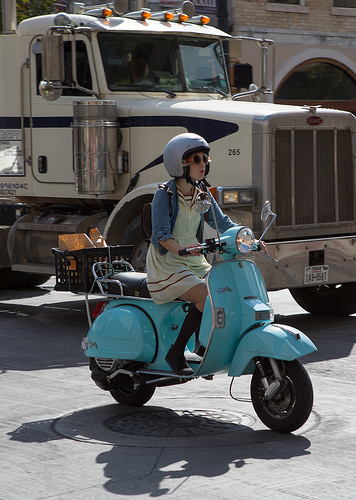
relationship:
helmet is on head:
[161, 133, 211, 179] [180, 150, 211, 192]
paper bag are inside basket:
[59, 227, 108, 251] [51, 244, 134, 292]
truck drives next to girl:
[0, 7, 356, 316] [146, 132, 267, 376]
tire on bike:
[248, 353, 314, 432] [80, 191, 318, 434]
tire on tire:
[109, 386, 156, 406] [248, 353, 314, 432]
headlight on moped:
[294, 109, 326, 128] [50, 190, 319, 434]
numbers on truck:
[227, 149, 240, 155] [0, 7, 356, 316]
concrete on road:
[0, 313, 352, 498] [0, 270, 330, 498]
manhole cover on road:
[101, 404, 257, 445] [0, 270, 330, 498]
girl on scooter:
[150, 133, 223, 203] [104, 273, 236, 384]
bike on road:
[80, 191, 318, 434] [0, 270, 330, 498]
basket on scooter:
[51, 244, 134, 292] [71, 241, 320, 442]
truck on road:
[7, 12, 354, 333] [0, 270, 330, 498]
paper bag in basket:
[57, 232, 95, 251] [51, 244, 134, 292]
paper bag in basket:
[59, 227, 108, 251] [51, 244, 134, 292]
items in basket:
[57, 225, 121, 270] [51, 238, 115, 277]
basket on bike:
[51, 238, 115, 277] [52, 190, 318, 432]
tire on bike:
[88, 345, 154, 411] [63, 200, 317, 442]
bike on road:
[84, 168, 323, 429] [0, 270, 330, 498]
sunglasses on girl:
[184, 149, 223, 180] [145, 133, 268, 376]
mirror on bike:
[191, 189, 212, 220] [107, 276, 182, 377]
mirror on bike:
[260, 198, 273, 231] [107, 276, 182, 377]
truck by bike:
[0, 7, 356, 316] [77, 233, 355, 370]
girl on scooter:
[145, 133, 268, 376] [40, 196, 319, 440]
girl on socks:
[145, 133, 268, 376] [168, 305, 207, 373]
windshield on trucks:
[114, 39, 224, 91] [1, 22, 331, 281]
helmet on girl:
[163, 132, 211, 179] [145, 133, 268, 376]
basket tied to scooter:
[51, 244, 134, 292] [40, 196, 319, 440]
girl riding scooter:
[145, 133, 268, 376] [83, 234, 316, 432]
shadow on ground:
[15, 399, 310, 498] [264, 81, 308, 128]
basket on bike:
[51, 244, 134, 292] [80, 191, 318, 434]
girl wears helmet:
[145, 133, 268, 376] [161, 133, 205, 184]